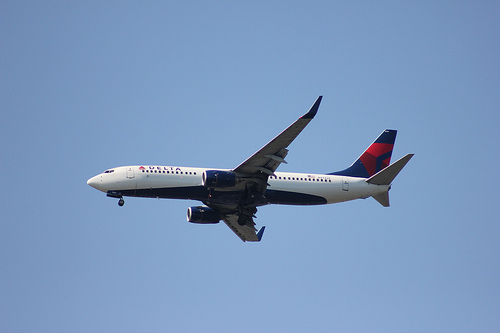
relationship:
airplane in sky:
[86, 95, 415, 243] [3, 0, 498, 325]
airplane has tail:
[86, 95, 415, 243] [335, 120, 428, 212]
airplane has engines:
[77, 94, 421, 244] [182, 164, 235, 224]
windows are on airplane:
[136, 163, 207, 177] [77, 94, 421, 244]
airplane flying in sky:
[86, 95, 415, 243] [3, 0, 498, 325]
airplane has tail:
[77, 94, 421, 244] [337, 120, 416, 210]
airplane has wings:
[77, 94, 421, 244] [204, 90, 329, 242]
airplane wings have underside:
[190, 81, 340, 272] [224, 95, 299, 245]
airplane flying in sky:
[77, 94, 421, 244] [3, 0, 498, 325]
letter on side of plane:
[157, 161, 177, 177] [93, 118, 419, 268]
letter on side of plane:
[171, 164, 183, 177] [69, 104, 426, 272]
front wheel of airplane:
[110, 190, 134, 215] [86, 95, 415, 243]